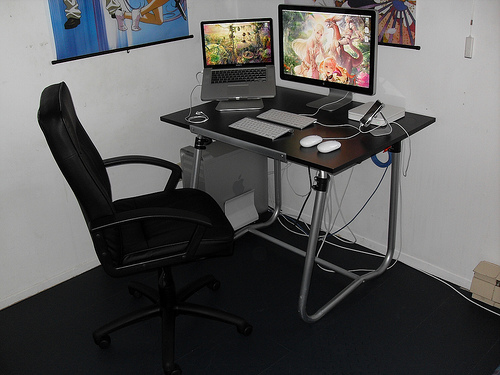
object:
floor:
[0, 209, 500, 374]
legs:
[190, 133, 400, 322]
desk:
[159, 81, 436, 323]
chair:
[37, 81, 253, 373]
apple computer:
[180, 140, 268, 230]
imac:
[277, 2, 378, 111]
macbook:
[200, 17, 276, 103]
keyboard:
[228, 115, 295, 140]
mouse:
[316, 139, 342, 154]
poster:
[43, 0, 194, 66]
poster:
[286, 0, 421, 50]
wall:
[237, 1, 500, 289]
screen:
[280, 8, 371, 89]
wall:
[0, 0, 240, 311]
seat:
[110, 186, 233, 265]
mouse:
[300, 135, 325, 146]